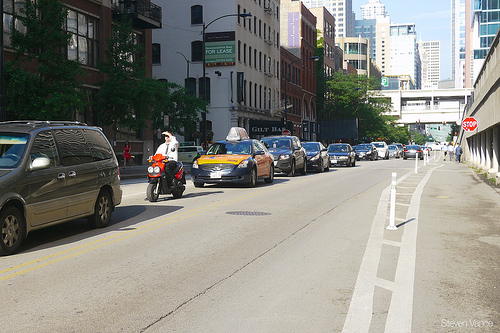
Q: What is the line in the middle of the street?
A: Dividing line.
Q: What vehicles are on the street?
A: Cars.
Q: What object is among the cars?
A: Motor scooter.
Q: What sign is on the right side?
A: Stop sign.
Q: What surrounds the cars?
A: Buildings.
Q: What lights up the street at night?
A: Street lights.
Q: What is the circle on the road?
A: Pothole cover.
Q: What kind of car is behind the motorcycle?
A: Taxi.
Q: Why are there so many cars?
A: Traffic.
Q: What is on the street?
A: Traffic.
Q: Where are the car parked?
A: In the sides of the road.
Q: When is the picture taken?
A: Daytime.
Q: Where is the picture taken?
A: On a city street.